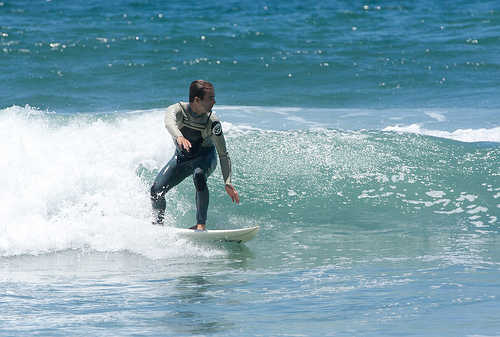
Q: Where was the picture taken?
A: The ocean.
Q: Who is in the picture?
A: A man.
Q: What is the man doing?
A: Surfing.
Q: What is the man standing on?
A: A surfboard.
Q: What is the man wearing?
A: A wetsuit.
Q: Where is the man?
A: The ocean.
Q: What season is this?
A: Summer.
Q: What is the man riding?
A: A surfboard.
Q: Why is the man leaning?
A: For balance.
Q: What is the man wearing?
A: A wetsuit.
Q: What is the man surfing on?
A: Water.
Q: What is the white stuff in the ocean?
A: Foam.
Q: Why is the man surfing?
A: Fun.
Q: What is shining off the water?
A: Sunlight.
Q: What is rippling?
A: Ocean.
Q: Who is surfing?
A: A man.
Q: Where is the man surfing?
A: Water.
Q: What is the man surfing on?
A: Surfboard.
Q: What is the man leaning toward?
A: Surfboard.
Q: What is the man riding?
A: A wave.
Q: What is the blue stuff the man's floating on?
A: Water.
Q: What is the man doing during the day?
A: Surfing.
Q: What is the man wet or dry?
A: Wet.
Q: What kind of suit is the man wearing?
A: Wet.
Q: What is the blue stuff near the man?
A: Water.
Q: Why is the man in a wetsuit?
A: To keep warm from the cold water.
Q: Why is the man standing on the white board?
A: The man is surfing.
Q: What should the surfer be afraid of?
A: Possibility of sharks.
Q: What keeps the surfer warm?
A: A blue and gray wetsuit.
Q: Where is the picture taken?
A: The ocean.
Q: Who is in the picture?
A: A man.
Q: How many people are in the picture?
A: One.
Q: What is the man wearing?
A: A wetsuit.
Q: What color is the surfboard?
A: White.